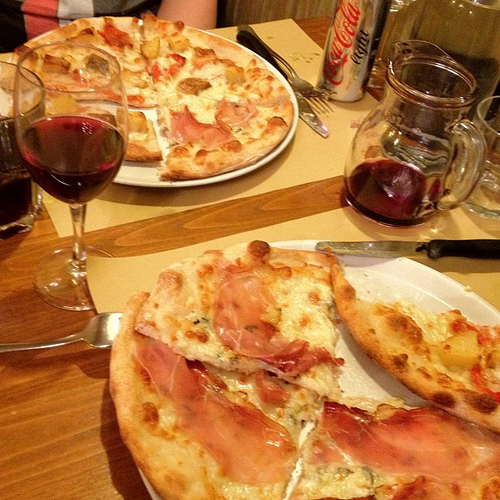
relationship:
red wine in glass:
[18, 114, 125, 206] [7, 34, 134, 314]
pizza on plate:
[1, 15, 293, 180] [15, 11, 298, 191]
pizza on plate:
[108, 238, 498, 498] [107, 237, 494, 498]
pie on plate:
[132, 241, 332, 406] [107, 237, 494, 498]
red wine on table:
[18, 117, 125, 207] [252, 180, 334, 225]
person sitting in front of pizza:
[15, 1, 117, 36] [108, 26, 240, 173]